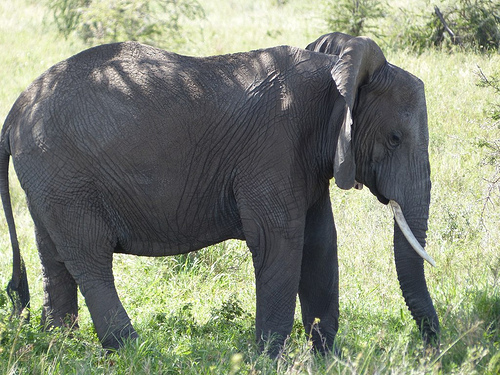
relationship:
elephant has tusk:
[0, 32, 446, 358] [386, 197, 442, 269]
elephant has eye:
[0, 32, 446, 358] [383, 130, 406, 146]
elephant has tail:
[0, 32, 446, 358] [3, 142, 42, 345]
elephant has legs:
[0, 32, 446, 358] [19, 193, 343, 371]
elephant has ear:
[0, 32, 446, 358] [328, 34, 384, 192]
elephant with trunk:
[0, 32, 446, 358] [392, 201, 445, 339]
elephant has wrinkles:
[0, 32, 446, 358] [44, 57, 427, 289]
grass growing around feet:
[11, 3, 498, 374] [43, 302, 302, 373]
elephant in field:
[0, 32, 446, 358] [10, 17, 492, 373]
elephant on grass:
[0, 32, 446, 358] [56, 312, 220, 373]